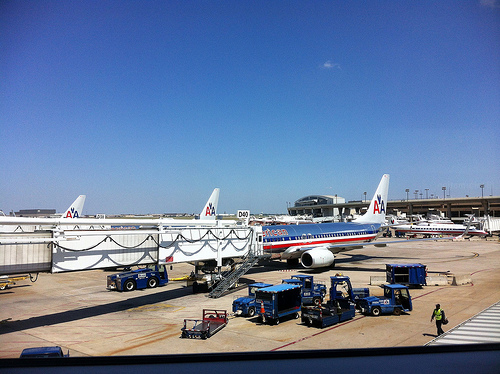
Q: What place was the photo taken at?
A: It was taken at the runway.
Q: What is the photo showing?
A: It is showing a runway.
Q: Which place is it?
A: It is a runway.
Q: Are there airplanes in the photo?
A: Yes, there is an airplane.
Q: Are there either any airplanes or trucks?
A: Yes, there is an airplane.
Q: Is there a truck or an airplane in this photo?
A: Yes, there is an airplane.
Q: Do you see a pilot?
A: No, there are no pilots.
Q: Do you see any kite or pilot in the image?
A: No, there are no pilots or kites.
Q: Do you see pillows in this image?
A: No, there are no pillows.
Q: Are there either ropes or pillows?
A: No, there are no pillows or ropes.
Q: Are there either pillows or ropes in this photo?
A: No, there are no pillows or ropes.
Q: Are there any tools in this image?
A: No, there are no tools.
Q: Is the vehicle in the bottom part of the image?
A: Yes, the vehicle is in the bottom of the image.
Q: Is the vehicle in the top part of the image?
A: No, the vehicle is in the bottom of the image.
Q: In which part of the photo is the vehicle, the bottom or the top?
A: The vehicle is in the bottom of the image.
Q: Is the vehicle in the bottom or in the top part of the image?
A: The vehicle is in the bottom of the image.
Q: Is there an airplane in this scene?
A: Yes, there is an airplane.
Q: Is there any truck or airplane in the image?
A: Yes, there is an airplane.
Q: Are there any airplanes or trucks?
A: Yes, there is an airplane.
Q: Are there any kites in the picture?
A: No, there are no kites.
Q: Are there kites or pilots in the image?
A: No, there are no kites or pilots.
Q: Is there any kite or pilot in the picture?
A: No, there are no kites or pilots.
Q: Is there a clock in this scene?
A: No, there are no clocks.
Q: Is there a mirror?
A: No, there are no mirrors.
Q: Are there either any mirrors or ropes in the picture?
A: No, there are no mirrors or ropes.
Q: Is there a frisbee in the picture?
A: No, there are no frisbees.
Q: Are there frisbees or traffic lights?
A: No, there are no frisbees or traffic lights.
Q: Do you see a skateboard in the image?
A: No, there are no skateboards.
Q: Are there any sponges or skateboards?
A: No, there are no skateboards or sponges.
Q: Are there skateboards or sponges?
A: No, there are no skateboards or sponges.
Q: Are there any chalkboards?
A: No, there are no chalkboards.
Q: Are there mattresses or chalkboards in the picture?
A: No, there are no chalkboards or mattresses.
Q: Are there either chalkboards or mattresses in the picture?
A: No, there are no chalkboards or mattresses.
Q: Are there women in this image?
A: No, there are no women.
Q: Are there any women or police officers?
A: No, there are no women or police officers.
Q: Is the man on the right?
A: Yes, the man is on the right of the image.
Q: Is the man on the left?
A: No, the man is on the right of the image.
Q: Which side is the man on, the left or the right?
A: The man is on the right of the image.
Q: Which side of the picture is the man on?
A: The man is on the right of the image.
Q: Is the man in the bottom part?
A: Yes, the man is in the bottom of the image.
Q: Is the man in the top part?
A: No, the man is in the bottom of the image.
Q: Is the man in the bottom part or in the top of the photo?
A: The man is in the bottom of the image.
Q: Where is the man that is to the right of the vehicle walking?
A: The man is walking on the runway.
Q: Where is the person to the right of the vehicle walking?
A: The man is walking on the runway.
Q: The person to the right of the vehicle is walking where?
A: The man is walking on the runway.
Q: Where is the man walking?
A: The man is walking on the runway.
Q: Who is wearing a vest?
A: The man is wearing a vest.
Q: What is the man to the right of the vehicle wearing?
A: The man is wearing a vest.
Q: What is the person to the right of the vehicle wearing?
A: The man is wearing a vest.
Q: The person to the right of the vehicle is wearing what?
A: The man is wearing a vest.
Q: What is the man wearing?
A: The man is wearing a vest.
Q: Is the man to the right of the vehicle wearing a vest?
A: Yes, the man is wearing a vest.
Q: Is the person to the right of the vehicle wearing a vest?
A: Yes, the man is wearing a vest.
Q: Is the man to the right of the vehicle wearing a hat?
A: No, the man is wearing a vest.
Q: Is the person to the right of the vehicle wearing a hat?
A: No, the man is wearing a vest.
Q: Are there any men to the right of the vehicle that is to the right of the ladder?
A: Yes, there is a man to the right of the vehicle.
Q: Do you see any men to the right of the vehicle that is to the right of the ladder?
A: Yes, there is a man to the right of the vehicle.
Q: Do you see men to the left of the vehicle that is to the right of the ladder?
A: No, the man is to the right of the vehicle.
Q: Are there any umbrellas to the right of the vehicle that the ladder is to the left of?
A: No, there is a man to the right of the vehicle.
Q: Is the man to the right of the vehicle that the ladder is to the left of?
A: Yes, the man is to the right of the vehicle.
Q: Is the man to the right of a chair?
A: No, the man is to the right of the vehicle.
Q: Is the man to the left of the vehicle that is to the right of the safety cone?
A: No, the man is to the right of the vehicle.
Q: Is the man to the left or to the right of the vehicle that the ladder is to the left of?
A: The man is to the right of the vehicle.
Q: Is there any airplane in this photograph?
A: Yes, there is an airplane.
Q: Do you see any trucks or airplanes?
A: Yes, there is an airplane.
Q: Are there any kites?
A: No, there are no kites.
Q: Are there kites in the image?
A: No, there are no kites.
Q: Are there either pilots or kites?
A: No, there are no kites or pilots.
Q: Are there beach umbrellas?
A: No, there are no beach umbrellas.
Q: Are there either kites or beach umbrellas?
A: No, there are no beach umbrellas or kites.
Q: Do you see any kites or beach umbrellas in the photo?
A: No, there are no beach umbrellas or kites.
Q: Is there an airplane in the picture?
A: Yes, there are airplanes.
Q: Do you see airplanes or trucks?
A: Yes, there are airplanes.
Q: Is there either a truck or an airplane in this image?
A: Yes, there are airplanes.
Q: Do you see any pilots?
A: No, there are no pilots.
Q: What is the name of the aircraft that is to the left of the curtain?
A: The aircraft is airplanes.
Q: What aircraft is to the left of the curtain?
A: The aircraft is airplanes.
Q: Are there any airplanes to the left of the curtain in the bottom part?
A: Yes, there are airplanes to the left of the curtain.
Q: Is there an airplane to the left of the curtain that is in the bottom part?
A: Yes, there are airplanes to the left of the curtain.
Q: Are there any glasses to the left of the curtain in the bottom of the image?
A: No, there are airplanes to the left of the curtain.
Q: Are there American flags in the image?
A: No, there are no American flags.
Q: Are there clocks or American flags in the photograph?
A: No, there are no American flags or clocks.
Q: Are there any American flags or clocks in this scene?
A: No, there are no American flags or clocks.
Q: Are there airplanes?
A: Yes, there is an airplane.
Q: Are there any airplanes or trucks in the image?
A: Yes, there is an airplane.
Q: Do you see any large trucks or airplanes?
A: Yes, there is a large airplane.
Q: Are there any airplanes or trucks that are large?
A: Yes, the airplane is large.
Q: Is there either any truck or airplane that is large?
A: Yes, the airplane is large.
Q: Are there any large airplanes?
A: Yes, there is a large airplane.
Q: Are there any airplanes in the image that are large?
A: Yes, there is an airplane that is large.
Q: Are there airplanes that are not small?
A: Yes, there is a large airplane.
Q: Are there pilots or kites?
A: No, there are no pilots or kites.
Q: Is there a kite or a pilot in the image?
A: No, there are no pilots or kites.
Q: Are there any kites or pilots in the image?
A: No, there are no pilots or kites.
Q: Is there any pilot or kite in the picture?
A: No, there are no pilots or kites.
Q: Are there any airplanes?
A: Yes, there are airplanes.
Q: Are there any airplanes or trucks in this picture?
A: Yes, there are airplanes.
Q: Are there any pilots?
A: No, there are no pilots.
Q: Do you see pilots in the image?
A: No, there are no pilots.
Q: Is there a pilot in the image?
A: No, there are no pilots.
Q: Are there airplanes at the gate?
A: Yes, there are airplanes at the gate.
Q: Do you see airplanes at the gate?
A: Yes, there are airplanes at the gate.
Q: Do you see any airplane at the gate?
A: Yes, there are airplanes at the gate.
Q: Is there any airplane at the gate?
A: Yes, there are airplanes at the gate.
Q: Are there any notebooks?
A: No, there are no notebooks.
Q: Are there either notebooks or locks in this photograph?
A: No, there are no notebooks or locks.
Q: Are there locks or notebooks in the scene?
A: No, there are no notebooks or locks.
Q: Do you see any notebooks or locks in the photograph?
A: No, there are no notebooks or locks.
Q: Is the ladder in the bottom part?
A: Yes, the ladder is in the bottom of the image.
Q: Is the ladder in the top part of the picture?
A: No, the ladder is in the bottom of the image.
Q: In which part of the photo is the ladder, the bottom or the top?
A: The ladder is in the bottom of the image.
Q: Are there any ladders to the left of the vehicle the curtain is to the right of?
A: Yes, there is a ladder to the left of the vehicle.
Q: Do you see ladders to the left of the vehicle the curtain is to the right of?
A: Yes, there is a ladder to the left of the vehicle.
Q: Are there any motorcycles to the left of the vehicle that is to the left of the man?
A: No, there is a ladder to the left of the vehicle.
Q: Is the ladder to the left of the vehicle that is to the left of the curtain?
A: Yes, the ladder is to the left of the vehicle.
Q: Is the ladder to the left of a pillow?
A: No, the ladder is to the left of the vehicle.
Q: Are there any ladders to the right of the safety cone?
A: Yes, there is a ladder to the right of the safety cone.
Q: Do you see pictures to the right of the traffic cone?
A: No, there is a ladder to the right of the traffic cone.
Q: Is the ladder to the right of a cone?
A: Yes, the ladder is to the right of a cone.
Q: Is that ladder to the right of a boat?
A: No, the ladder is to the right of a cone.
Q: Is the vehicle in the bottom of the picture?
A: Yes, the vehicle is in the bottom of the image.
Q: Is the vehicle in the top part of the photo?
A: No, the vehicle is in the bottom of the image.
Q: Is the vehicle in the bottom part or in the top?
A: The vehicle is in the bottom of the image.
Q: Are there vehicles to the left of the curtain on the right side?
A: Yes, there is a vehicle to the left of the curtain.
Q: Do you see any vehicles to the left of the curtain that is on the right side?
A: Yes, there is a vehicle to the left of the curtain.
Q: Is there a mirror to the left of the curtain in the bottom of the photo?
A: No, there is a vehicle to the left of the curtain.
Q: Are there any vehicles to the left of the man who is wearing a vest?
A: Yes, there is a vehicle to the left of the man.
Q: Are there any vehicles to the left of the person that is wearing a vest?
A: Yes, there is a vehicle to the left of the man.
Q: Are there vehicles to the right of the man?
A: No, the vehicle is to the left of the man.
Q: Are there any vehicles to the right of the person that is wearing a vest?
A: No, the vehicle is to the left of the man.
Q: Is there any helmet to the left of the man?
A: No, there is a vehicle to the left of the man.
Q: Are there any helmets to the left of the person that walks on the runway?
A: No, there is a vehicle to the left of the man.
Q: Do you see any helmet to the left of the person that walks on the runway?
A: No, there is a vehicle to the left of the man.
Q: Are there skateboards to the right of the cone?
A: No, there is a vehicle to the right of the cone.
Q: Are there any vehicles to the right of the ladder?
A: Yes, there is a vehicle to the right of the ladder.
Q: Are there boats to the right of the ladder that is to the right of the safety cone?
A: No, there is a vehicle to the right of the ladder.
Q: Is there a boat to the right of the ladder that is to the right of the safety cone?
A: No, there is a vehicle to the right of the ladder.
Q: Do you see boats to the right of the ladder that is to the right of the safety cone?
A: No, there is a vehicle to the right of the ladder.